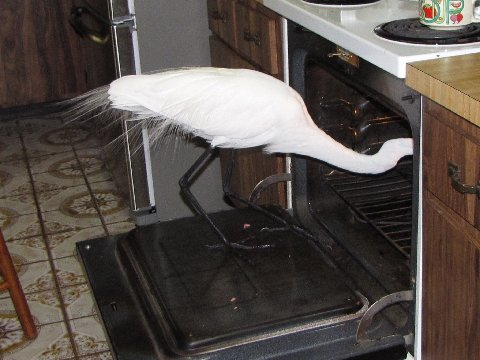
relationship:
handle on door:
[52, 6, 110, 50] [63, 0, 165, 216]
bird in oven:
[54, 67, 414, 250] [77, 60, 477, 354]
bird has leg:
[51, 54, 477, 235] [179, 148, 224, 237]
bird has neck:
[54, 67, 414, 250] [310, 118, 414, 174]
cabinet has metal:
[399, 55, 479, 355] [446, 164, 478, 196]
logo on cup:
[421, 2, 438, 19] [415, 1, 479, 33]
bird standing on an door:
[54, 67, 414, 250] [78, 209, 402, 360]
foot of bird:
[223, 218, 267, 241] [41, 53, 418, 265]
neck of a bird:
[349, 125, 399, 188] [54, 67, 414, 250]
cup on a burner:
[419, 0, 473, 31] [374, 13, 478, 46]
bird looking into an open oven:
[54, 67, 414, 250] [286, 25, 425, 339]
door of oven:
[71, 202, 411, 358] [285, 15, 423, 330]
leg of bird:
[181, 148, 266, 258] [54, 67, 414, 250]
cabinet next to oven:
[406, 53, 480, 360] [275, 14, 426, 347]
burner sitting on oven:
[374, 17, 480, 47] [65, 15, 424, 358]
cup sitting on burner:
[411, 0, 478, 34] [374, 9, 478, 50]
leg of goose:
[179, 148, 224, 237] [48, 66, 412, 264]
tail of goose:
[63, 70, 156, 122] [59, 57, 415, 253]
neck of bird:
[310, 118, 414, 174] [54, 67, 414, 250]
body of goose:
[140, 65, 306, 147] [48, 66, 412, 264]